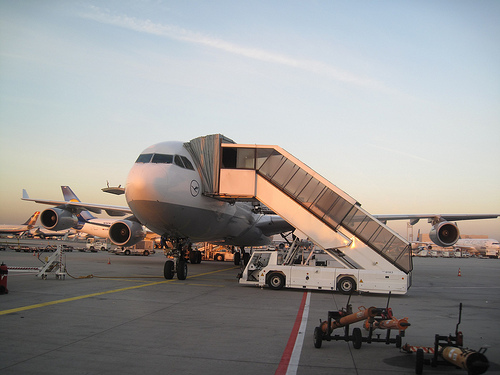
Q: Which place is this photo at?
A: It is at the runway.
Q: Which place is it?
A: It is a runway.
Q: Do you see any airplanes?
A: Yes, there is an airplane.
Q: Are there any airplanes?
A: Yes, there is an airplane.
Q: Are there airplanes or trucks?
A: Yes, there is an airplane.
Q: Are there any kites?
A: No, there are no kites.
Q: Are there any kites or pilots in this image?
A: No, there are no kites or pilots.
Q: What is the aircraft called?
A: The aircraft is an airplane.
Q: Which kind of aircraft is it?
A: The aircraft is an airplane.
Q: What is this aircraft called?
A: This is an airplane.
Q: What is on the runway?
A: The airplane is on the runway.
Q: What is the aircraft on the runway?
A: The aircraft is an airplane.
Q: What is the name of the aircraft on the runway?
A: The aircraft is an airplane.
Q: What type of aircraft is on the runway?
A: The aircraft is an airplane.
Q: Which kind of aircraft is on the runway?
A: The aircraft is an airplane.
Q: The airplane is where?
A: The airplane is on the runway.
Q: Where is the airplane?
A: The airplane is on the runway.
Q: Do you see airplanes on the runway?
A: Yes, there is an airplane on the runway.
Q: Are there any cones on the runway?
A: No, there is an airplane on the runway.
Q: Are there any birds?
A: No, there are no birds.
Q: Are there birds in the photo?
A: No, there are no birds.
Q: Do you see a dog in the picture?
A: No, there are no dogs.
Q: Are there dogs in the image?
A: No, there are no dogs.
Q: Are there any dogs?
A: No, there are no dogs.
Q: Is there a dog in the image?
A: No, there are no dogs.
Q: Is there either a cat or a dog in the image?
A: No, there are no dogs or cats.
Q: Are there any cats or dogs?
A: No, there are no dogs or cats.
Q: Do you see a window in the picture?
A: Yes, there is a window.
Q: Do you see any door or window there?
A: Yes, there is a window.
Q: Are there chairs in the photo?
A: No, there are no chairs.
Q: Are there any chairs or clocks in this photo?
A: No, there are no chairs or clocks.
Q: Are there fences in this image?
A: No, there are no fences.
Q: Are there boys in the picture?
A: No, there are no boys.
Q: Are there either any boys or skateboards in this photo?
A: No, there are no boys or skateboards.